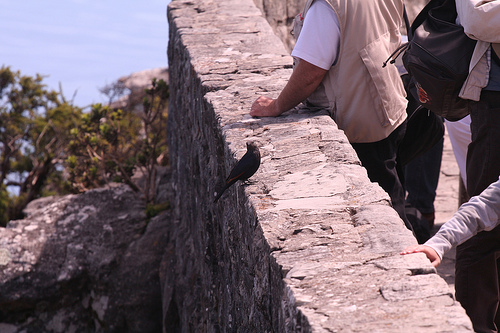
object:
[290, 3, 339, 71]
white shirt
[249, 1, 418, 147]
man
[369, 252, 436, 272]
rocks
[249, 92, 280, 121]
hand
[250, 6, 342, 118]
arm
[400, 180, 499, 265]
arm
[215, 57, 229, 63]
rock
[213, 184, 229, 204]
tail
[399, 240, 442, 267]
hand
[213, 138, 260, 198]
bird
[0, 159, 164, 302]
boulder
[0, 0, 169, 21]
sky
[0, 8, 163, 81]
water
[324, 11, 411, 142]
tan vest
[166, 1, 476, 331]
rock wall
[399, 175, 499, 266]
person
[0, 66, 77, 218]
trees